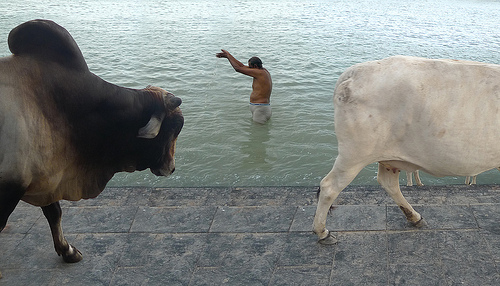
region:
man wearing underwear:
[212, 47, 275, 131]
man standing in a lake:
[214, 43, 276, 128]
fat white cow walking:
[310, 53, 499, 251]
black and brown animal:
[2, 19, 185, 264]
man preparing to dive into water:
[212, 45, 274, 126]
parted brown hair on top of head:
[142, 80, 170, 119]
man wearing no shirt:
[211, 48, 274, 127]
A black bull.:
[0, 20, 197, 262]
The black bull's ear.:
[139, 112, 172, 147]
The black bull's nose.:
[168, 165, 182, 173]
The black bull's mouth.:
[153, 165, 172, 178]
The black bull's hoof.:
[46, 240, 86, 261]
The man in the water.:
[214, 44, 285, 131]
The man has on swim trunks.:
[242, 99, 277, 125]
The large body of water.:
[2, 1, 495, 165]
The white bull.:
[314, 41, 499, 256]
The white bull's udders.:
[396, 170, 438, 199]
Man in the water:
[206, 34, 291, 142]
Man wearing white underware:
[222, 39, 289, 136]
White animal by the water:
[299, 35, 481, 273]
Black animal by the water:
[11, 7, 201, 282]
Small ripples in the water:
[281, 41, 318, 94]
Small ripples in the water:
[205, 149, 239, 178]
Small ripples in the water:
[250, 131, 283, 165]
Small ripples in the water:
[424, 21, 468, 42]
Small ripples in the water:
[107, 9, 152, 53]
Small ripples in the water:
[168, 61, 214, 92]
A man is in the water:
[209, 40, 297, 152]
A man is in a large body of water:
[202, 31, 301, 147]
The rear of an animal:
[303, 35, 455, 248]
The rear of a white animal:
[308, 36, 452, 258]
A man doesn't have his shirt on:
[210, 36, 292, 131]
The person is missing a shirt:
[213, 40, 290, 140]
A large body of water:
[108, 11, 174, 55]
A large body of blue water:
[107, 7, 188, 57]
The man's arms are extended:
[213, 45, 276, 100]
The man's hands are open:
[213, 45, 271, 87]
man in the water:
[191, 22, 311, 132]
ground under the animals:
[113, 180, 295, 281]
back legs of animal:
[281, 142, 428, 257]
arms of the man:
[208, 44, 248, 94]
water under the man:
[181, 115, 249, 186]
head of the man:
[237, 42, 273, 82]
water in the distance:
[279, 3, 349, 70]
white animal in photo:
[281, 51, 493, 220]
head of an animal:
[123, 69, 206, 196]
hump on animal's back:
[5, 5, 100, 81]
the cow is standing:
[1, 19, 183, 259]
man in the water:
[216, 48, 271, 125]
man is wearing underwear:
[248, 103, 270, 124]